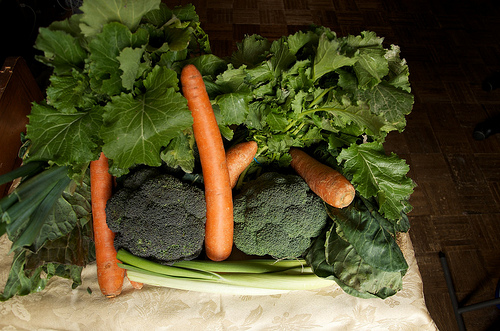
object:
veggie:
[104, 165, 211, 265]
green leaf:
[333, 139, 415, 225]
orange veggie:
[87, 152, 125, 299]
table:
[0, 227, 443, 331]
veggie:
[229, 172, 328, 262]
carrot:
[180, 63, 234, 262]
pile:
[0, 0, 417, 303]